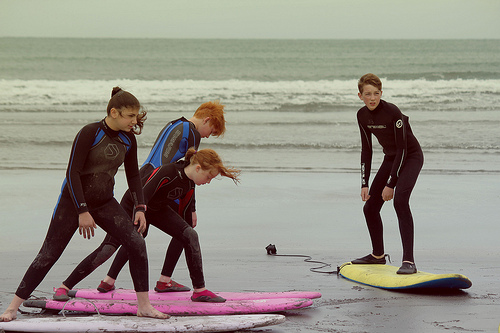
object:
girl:
[53, 149, 226, 302]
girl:
[0, 87, 170, 322]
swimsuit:
[356, 99, 424, 264]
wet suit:
[355, 99, 423, 264]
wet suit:
[106, 116, 201, 280]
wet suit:
[62, 163, 206, 291]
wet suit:
[13, 120, 147, 301]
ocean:
[0, 35, 500, 174]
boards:
[54, 289, 324, 302]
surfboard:
[22, 297, 312, 316]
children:
[350, 73, 424, 274]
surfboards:
[0, 313, 282, 333]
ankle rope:
[275, 255, 336, 273]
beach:
[0, 165, 500, 333]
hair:
[106, 87, 147, 135]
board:
[339, 264, 472, 289]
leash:
[258, 230, 340, 289]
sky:
[0, 1, 498, 40]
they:
[0, 73, 424, 322]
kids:
[96, 102, 225, 293]